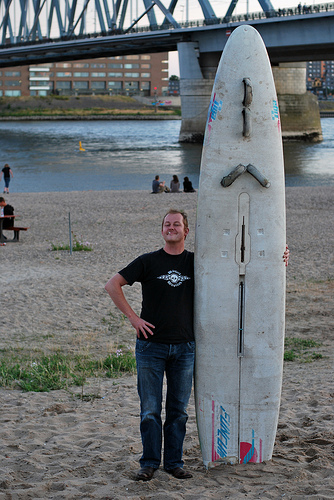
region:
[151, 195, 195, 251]
head of a person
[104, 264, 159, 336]
arm of a person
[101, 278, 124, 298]
elbow of a person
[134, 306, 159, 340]
hand of a person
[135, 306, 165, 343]
fingers of a person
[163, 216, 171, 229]
eye of a person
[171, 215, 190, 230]
eye of a person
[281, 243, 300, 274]
fingers of a person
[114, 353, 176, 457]
leg of a person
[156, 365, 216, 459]
leg of a person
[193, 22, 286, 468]
a white board in the sand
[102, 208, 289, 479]
a man with his arm around a board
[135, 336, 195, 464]
blue jeans on a man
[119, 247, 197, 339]
a black shirt on a man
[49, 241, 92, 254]
a patch of grass in the sand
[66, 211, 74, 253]
a pipe sticking out of the ground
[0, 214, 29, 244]
a picnic table on the sand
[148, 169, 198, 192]
three people sitting next to the water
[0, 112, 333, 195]
water running under a bridge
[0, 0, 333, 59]
a bridge over the water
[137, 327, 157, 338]
finger of a person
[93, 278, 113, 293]
elbow of a person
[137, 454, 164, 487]
feet of a person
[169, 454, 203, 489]
feet of a person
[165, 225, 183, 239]
mouth of a person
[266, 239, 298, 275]
finger of a person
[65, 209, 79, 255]
a pipe sticking out of the sand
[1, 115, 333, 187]
a river running past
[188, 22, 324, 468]
a very tall surfboard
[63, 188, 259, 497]
a man next to surfboard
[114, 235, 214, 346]
a black shirt with white design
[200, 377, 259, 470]
blue letters on surfboard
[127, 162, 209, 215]
three people sitting on beach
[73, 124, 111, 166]
something yellow in the water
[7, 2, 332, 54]
a bridge over the water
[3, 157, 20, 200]
a person walking on the beach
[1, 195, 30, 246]
a person sitting on a bench